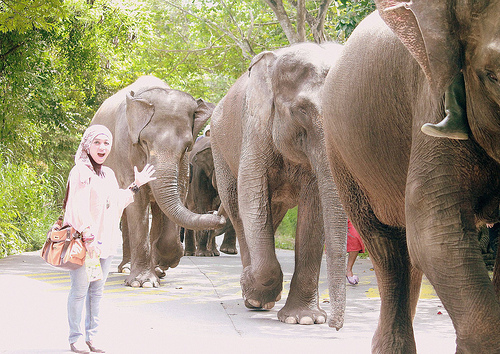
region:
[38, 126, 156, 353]
a woman with her mouth wide open.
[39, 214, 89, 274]
a brown purse.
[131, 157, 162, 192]
an open human hand.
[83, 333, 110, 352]
the left shoe of a woman.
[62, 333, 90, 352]
the right shoe of a woman.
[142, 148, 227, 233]
an elephants trunk.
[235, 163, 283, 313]
the right front leg of an elephant.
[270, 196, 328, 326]
the left front leg of an elephant.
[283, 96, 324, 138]
the right eye of an elephant.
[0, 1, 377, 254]
a forest filled with green plants.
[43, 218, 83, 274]
the brown bag on a woman's shoulder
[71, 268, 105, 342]
blue jeans on a woman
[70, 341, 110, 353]
a pair of flat shoes on a woman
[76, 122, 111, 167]
a woman with a scarf over her hair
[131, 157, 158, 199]
a woman's open left hand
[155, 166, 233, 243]
an elephant's trunk bent to the right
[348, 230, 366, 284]
the red shorts on a person behind an elephant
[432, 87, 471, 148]
a black boot on a person's foot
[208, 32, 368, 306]
an elephant walking between two other elephants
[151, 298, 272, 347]
a concrete path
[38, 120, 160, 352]
Woman showing excitement on her face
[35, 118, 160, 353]
woman holding shoulder bag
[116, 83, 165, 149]
Folded brown elephant's ear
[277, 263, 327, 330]
Elephant's foot on concrete walk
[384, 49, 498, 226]
Dangling elephant rider's foot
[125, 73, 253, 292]
Small elephant following in the distance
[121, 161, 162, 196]
Bracelet on a woman's wrist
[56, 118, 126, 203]
Woman wearing a headscarf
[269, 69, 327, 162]
The eye of an elephant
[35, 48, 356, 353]
Woman standing near elephants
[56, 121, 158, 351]
A woman with her head wrapped standing by elephants.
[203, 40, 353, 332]
The second elephant in the sequence.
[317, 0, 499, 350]
The first elephant in a sequence of elephants.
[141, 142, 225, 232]
A long curved trunk on the third elephant.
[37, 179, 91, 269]
A woman's purse.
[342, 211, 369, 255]
A red cloth on a person walking to the right of elephants.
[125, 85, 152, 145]
An elephants right side ear.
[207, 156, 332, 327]
Three visible legs on the second elephant.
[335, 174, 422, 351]
Back legs of the first elephant.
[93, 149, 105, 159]
Open mouth of a woman with her hand in the air.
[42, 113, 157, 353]
woman who is surprised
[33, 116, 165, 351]
woman with kerchief and purse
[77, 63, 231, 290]
grey elephant flapping ears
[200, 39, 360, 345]
grey elephant with long trunk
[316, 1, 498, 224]
elephant giving a ride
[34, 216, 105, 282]
brown and tan striped purse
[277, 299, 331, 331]
elephant toes with white nails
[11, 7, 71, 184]
yellow green leaves near elephants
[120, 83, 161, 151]
flapping ear on a gray elephant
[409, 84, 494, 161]
green boot near an elephant